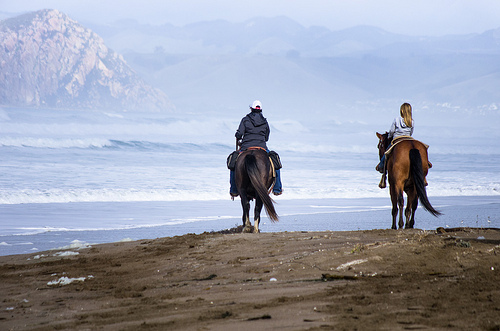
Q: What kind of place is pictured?
A: It is a shore.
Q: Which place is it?
A: It is a shore.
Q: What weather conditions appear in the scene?
A: It is foggy.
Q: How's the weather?
A: It is foggy.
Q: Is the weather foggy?
A: Yes, it is foggy.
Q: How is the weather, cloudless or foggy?
A: It is foggy.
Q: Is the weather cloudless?
A: No, it is foggy.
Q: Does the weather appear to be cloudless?
A: No, it is foggy.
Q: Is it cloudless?
A: No, it is foggy.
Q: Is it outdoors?
A: Yes, it is outdoors.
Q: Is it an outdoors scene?
A: Yes, it is outdoors.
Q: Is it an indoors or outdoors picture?
A: It is outdoors.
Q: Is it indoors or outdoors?
A: It is outdoors.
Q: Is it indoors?
A: No, it is outdoors.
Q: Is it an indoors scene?
A: No, it is outdoors.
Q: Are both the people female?
A: No, they are both male and female.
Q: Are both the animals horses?
A: Yes, all the animals are horses.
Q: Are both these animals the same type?
A: Yes, all the animals are horses.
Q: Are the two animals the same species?
A: Yes, all the animals are horses.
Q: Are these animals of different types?
A: No, all the animals are horses.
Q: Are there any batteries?
A: No, there are no batteries.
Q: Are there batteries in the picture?
A: No, there are no batteries.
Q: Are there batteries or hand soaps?
A: No, there are no batteries or hand soaps.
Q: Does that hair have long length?
A: Yes, the hair is long.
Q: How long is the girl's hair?
A: The hair is long.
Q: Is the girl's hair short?
A: No, the hair is long.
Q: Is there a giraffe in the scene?
A: No, there are no giraffes.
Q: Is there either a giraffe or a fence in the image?
A: No, there are no giraffes or fences.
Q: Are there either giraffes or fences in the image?
A: No, there are no giraffes or fences.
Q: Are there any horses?
A: Yes, there is a horse.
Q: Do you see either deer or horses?
A: Yes, there is a horse.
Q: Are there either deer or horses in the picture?
A: Yes, there is a horse.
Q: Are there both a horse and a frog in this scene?
A: No, there is a horse but no frogs.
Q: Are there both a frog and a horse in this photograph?
A: No, there is a horse but no frogs.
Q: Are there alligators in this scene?
A: No, there are no alligators.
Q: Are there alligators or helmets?
A: No, there are no alligators or helmets.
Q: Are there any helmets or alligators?
A: No, there are no alligators or helmets.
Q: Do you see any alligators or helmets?
A: No, there are no alligators or helmets.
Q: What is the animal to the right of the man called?
A: The animal is a horse.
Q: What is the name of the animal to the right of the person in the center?
A: The animal is a horse.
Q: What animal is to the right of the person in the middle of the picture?
A: The animal is a horse.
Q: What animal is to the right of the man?
A: The animal is a horse.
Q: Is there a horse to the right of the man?
A: Yes, there is a horse to the right of the man.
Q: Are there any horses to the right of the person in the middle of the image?
A: Yes, there is a horse to the right of the man.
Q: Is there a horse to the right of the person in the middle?
A: Yes, there is a horse to the right of the man.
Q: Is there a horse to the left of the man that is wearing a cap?
A: No, the horse is to the right of the man.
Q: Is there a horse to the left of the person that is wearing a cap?
A: No, the horse is to the right of the man.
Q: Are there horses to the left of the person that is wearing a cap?
A: No, the horse is to the right of the man.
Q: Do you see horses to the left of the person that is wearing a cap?
A: No, the horse is to the right of the man.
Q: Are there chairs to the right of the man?
A: No, there is a horse to the right of the man.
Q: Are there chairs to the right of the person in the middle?
A: No, there is a horse to the right of the man.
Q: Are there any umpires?
A: No, there are no umpires.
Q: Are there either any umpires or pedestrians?
A: No, there are no umpires or pedestrians.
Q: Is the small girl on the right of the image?
A: Yes, the girl is on the right of the image.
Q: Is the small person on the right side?
A: Yes, the girl is on the right of the image.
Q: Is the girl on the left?
A: No, the girl is on the right of the image.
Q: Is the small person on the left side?
A: No, the girl is on the right of the image.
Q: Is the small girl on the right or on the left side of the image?
A: The girl is on the right of the image.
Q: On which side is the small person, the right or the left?
A: The girl is on the right of the image.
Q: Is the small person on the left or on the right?
A: The girl is on the right of the image.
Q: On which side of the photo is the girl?
A: The girl is on the right of the image.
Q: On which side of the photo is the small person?
A: The girl is on the right of the image.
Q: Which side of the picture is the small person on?
A: The girl is on the right of the image.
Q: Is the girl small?
A: Yes, the girl is small.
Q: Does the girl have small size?
A: Yes, the girl is small.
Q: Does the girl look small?
A: Yes, the girl is small.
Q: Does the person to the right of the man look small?
A: Yes, the girl is small.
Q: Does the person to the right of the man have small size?
A: Yes, the girl is small.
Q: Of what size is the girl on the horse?
A: The girl is small.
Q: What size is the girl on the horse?
A: The girl is small.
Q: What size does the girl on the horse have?
A: The girl has small size.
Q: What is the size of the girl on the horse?
A: The girl is small.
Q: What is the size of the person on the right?
A: The girl is small.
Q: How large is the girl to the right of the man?
A: The girl is small.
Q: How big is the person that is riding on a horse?
A: The girl is small.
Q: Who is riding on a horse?
A: The girl is riding on a horse.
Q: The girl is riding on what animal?
A: The girl is riding on a horse.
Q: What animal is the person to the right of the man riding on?
A: The girl is riding on a horse.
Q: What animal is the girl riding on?
A: The girl is riding on a horse.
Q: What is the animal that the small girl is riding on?
A: The animal is a horse.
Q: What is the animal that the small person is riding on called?
A: The animal is a horse.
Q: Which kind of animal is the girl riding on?
A: The girl is riding on a horse.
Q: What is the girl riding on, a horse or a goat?
A: The girl is riding on a horse.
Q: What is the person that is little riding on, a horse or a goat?
A: The girl is riding on a horse.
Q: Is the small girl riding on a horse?
A: Yes, the girl is riding on a horse.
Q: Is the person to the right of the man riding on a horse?
A: Yes, the girl is riding on a horse.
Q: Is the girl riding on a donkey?
A: No, the girl is riding on a horse.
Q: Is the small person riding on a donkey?
A: No, the girl is riding on a horse.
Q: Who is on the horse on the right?
A: The girl is on the horse.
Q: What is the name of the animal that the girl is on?
A: The animal is a horse.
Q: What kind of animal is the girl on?
A: The girl is on the horse.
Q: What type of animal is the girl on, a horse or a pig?
A: The girl is on a horse.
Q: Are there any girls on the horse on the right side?
A: Yes, there is a girl on the horse.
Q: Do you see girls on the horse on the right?
A: Yes, there is a girl on the horse.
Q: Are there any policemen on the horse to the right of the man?
A: No, there is a girl on the horse.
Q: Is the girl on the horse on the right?
A: Yes, the girl is on the horse.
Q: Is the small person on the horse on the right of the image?
A: Yes, the girl is on the horse.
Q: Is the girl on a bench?
A: No, the girl is on the horse.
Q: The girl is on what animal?
A: The girl is on the horse.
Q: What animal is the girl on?
A: The girl is on the horse.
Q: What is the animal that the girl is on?
A: The animal is a horse.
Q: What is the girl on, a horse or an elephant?
A: The girl is on a horse.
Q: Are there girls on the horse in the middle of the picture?
A: Yes, there is a girl on the horse.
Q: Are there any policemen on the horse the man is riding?
A: No, there is a girl on the horse.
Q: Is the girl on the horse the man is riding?
A: Yes, the girl is on the horse.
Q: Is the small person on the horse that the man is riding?
A: Yes, the girl is on the horse.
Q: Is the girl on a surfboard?
A: No, the girl is on the horse.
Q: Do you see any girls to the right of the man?
A: Yes, there is a girl to the right of the man.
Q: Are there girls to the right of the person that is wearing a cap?
A: Yes, there is a girl to the right of the man.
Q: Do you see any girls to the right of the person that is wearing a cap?
A: Yes, there is a girl to the right of the man.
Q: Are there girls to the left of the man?
A: No, the girl is to the right of the man.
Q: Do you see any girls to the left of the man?
A: No, the girl is to the right of the man.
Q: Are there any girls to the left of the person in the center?
A: No, the girl is to the right of the man.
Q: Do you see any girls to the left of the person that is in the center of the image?
A: No, the girl is to the right of the man.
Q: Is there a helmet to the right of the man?
A: No, there is a girl to the right of the man.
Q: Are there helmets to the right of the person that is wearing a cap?
A: No, there is a girl to the right of the man.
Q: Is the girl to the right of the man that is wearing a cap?
A: Yes, the girl is to the right of the man.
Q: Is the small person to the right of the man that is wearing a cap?
A: Yes, the girl is to the right of the man.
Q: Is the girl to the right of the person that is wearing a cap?
A: Yes, the girl is to the right of the man.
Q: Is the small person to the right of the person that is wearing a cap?
A: Yes, the girl is to the right of the man.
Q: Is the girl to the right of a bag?
A: No, the girl is to the right of the man.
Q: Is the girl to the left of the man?
A: No, the girl is to the right of the man.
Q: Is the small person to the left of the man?
A: No, the girl is to the right of the man.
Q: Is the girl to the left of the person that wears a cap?
A: No, the girl is to the right of the man.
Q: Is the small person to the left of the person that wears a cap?
A: No, the girl is to the right of the man.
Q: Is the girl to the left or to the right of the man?
A: The girl is to the right of the man.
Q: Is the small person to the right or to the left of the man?
A: The girl is to the right of the man.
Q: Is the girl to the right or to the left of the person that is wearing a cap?
A: The girl is to the right of the man.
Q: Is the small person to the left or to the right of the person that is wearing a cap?
A: The girl is to the right of the man.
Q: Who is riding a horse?
A: The girl is riding a horse.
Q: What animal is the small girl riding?
A: The girl is riding a horse.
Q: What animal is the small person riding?
A: The girl is riding a horse.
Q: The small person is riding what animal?
A: The girl is riding a horse.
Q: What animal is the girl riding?
A: The girl is riding a horse.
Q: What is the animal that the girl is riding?
A: The animal is a horse.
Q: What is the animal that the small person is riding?
A: The animal is a horse.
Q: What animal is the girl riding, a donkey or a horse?
A: The girl is riding a horse.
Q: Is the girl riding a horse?
A: Yes, the girl is riding a horse.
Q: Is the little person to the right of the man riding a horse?
A: Yes, the girl is riding a horse.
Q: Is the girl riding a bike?
A: No, the girl is riding a horse.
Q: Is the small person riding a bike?
A: No, the girl is riding a horse.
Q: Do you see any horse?
A: Yes, there is a horse.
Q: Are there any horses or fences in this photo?
A: Yes, there is a horse.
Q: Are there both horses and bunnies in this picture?
A: No, there is a horse but no bunnies.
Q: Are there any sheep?
A: No, there are no sheep.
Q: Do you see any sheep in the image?
A: No, there is no sheep.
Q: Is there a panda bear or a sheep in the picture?
A: No, there are no sheep or pandas.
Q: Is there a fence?
A: No, there are no fences.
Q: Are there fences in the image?
A: No, there are no fences.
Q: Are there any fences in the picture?
A: No, there are no fences.